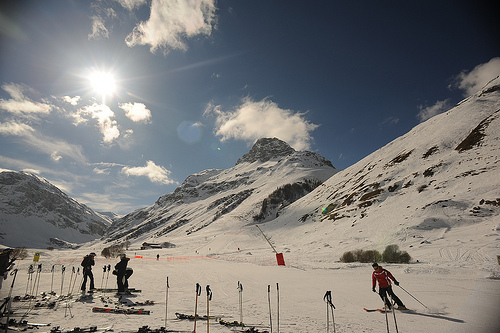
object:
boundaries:
[56, 256, 215, 264]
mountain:
[77, 137, 339, 250]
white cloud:
[192, 83, 322, 153]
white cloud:
[415, 55, 500, 123]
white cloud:
[87, 0, 219, 57]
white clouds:
[0, 82, 180, 217]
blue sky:
[0, 0, 498, 218]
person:
[0, 248, 14, 290]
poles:
[206, 285, 210, 332]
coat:
[371, 266, 394, 288]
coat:
[112, 260, 132, 292]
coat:
[81, 254, 95, 271]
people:
[371, 263, 409, 310]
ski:
[377, 309, 393, 313]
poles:
[381, 287, 389, 333]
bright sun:
[88, 69, 121, 96]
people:
[111, 254, 133, 292]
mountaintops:
[236, 137, 294, 163]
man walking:
[81, 252, 97, 290]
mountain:
[0, 172, 124, 250]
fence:
[56, 256, 215, 265]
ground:
[0, 248, 500, 333]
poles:
[387, 285, 398, 332]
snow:
[0, 79, 500, 333]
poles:
[398, 286, 439, 316]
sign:
[32, 252, 40, 262]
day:
[0, 52, 500, 215]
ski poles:
[5, 267, 285, 326]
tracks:
[0, 248, 500, 332]